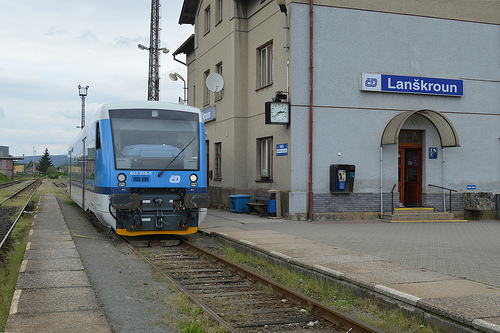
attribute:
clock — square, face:
[265, 99, 290, 126]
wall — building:
[243, 17, 313, 220]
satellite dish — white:
[204, 70, 223, 90]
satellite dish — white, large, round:
[204, 70, 226, 95]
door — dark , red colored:
[393, 128, 424, 208]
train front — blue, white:
[95, 99, 212, 237]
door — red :
[401, 149, 424, 207]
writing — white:
[387, 76, 459, 93]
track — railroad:
[138, 241, 375, 331]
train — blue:
[58, 94, 215, 244]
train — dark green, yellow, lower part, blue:
[64, 100, 211, 245]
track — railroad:
[119, 235, 374, 332]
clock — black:
[264, 98, 294, 129]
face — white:
[269, 103, 286, 123]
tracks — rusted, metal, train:
[149, 242, 384, 331]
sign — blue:
[312, 59, 496, 101]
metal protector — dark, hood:
[315, 148, 373, 204]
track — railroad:
[0, 175, 41, 261]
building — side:
[168, 2, 484, 215]